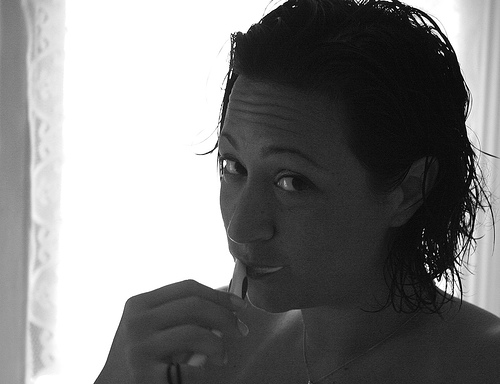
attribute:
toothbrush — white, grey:
[181, 254, 251, 374]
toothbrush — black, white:
[189, 230, 276, 351]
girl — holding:
[122, 30, 456, 369]